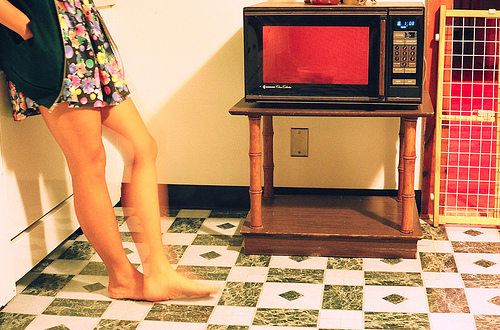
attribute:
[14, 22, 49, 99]
pocket — black 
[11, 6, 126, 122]
floral skirt — floral 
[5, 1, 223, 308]
woman — leaning 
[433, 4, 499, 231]
gate — wooden 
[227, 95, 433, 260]
stand — stable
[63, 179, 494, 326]
floor — tile, checkered 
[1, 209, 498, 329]
floor tiles — checkered 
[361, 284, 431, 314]
tile — White 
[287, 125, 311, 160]
socket — silver 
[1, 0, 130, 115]
clothing — floral 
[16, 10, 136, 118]
floral pattern — floral 